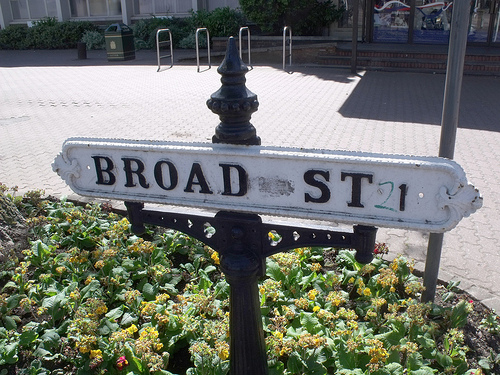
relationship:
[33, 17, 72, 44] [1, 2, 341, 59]
plant side wall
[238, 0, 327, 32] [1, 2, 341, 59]
plant side wall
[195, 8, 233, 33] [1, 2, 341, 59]
plant side wall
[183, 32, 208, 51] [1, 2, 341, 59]
plant side wall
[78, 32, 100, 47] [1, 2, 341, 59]
plant side wall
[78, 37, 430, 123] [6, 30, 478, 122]
shadow on pathway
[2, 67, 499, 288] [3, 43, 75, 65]
pathway made of concrete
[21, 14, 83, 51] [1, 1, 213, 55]
bush front building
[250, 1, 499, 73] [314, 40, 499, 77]
building has steps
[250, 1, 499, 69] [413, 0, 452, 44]
building has window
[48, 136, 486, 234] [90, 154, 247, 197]
board has black lettering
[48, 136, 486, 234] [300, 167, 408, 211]
board has black lettering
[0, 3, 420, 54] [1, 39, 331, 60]
shrubs in planter